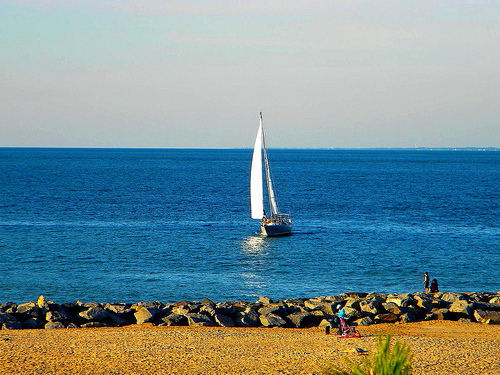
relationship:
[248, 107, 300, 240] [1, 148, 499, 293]
boat on water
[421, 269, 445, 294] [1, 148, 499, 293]
people by water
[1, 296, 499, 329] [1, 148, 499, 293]
rocks near water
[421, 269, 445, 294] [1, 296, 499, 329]
people on rocks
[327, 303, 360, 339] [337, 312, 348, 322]
person wearing shirt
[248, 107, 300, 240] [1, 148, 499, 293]
boat in water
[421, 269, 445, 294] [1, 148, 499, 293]
people near water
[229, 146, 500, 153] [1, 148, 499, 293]
city near water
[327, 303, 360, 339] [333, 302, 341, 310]
person wearing hat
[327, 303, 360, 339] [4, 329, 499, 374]
person on beach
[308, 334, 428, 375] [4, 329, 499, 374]
plant near beach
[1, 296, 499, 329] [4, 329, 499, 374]
rocks near beach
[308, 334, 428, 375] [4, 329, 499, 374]
plant on beach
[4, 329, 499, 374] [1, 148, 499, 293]
beach near water